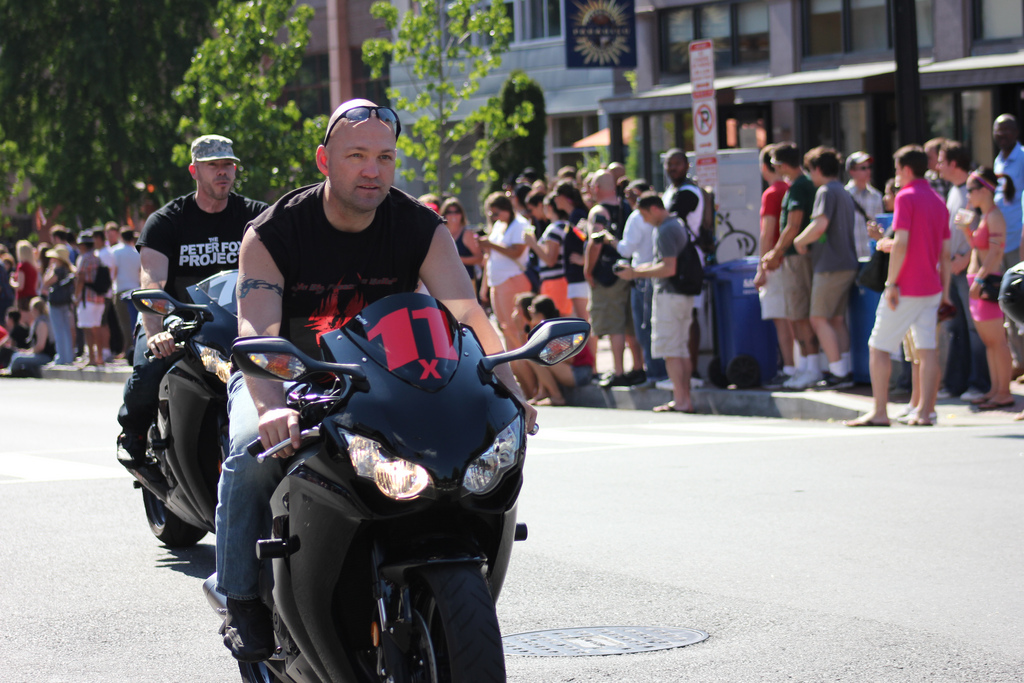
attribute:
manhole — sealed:
[564, 603, 625, 666]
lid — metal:
[495, 614, 716, 679]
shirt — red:
[877, 176, 962, 297]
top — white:
[475, 215, 543, 293]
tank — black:
[242, 175, 456, 368]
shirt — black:
[118, 188, 266, 338]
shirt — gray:
[648, 204, 688, 291]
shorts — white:
[851, 286, 949, 360]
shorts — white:
[639, 288, 702, 368]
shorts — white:
[749, 253, 801, 327]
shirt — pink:
[881, 182, 953, 304]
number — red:
[375, 297, 462, 377]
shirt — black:
[268, 212, 450, 306]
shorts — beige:
[814, 269, 860, 319]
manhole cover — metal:
[503, 621, 728, 661]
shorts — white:
[873, 286, 951, 349]